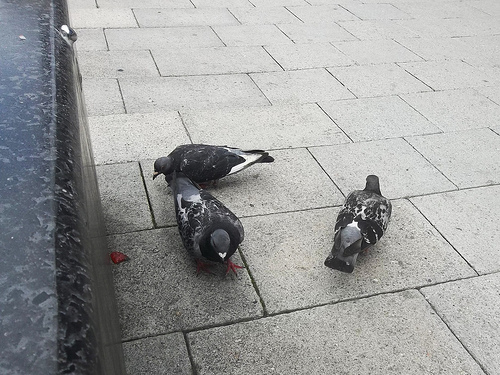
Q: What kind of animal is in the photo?
A: Pigeons.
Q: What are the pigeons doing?
A: Standing on the ground.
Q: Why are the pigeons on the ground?
A: They are looking for food.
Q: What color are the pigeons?
A: Gray and white.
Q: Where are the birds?
A: On the ground.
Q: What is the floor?
A: Cement tiles.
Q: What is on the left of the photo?
A: A black stone slab.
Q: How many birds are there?
A: Three.